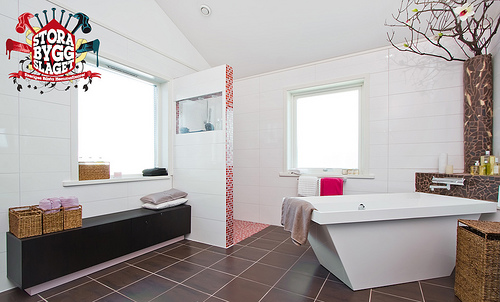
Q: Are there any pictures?
A: No, there are no pictures.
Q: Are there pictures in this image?
A: No, there are no pictures.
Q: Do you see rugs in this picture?
A: No, there are no rugs.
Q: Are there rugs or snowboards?
A: No, there are no rugs or snowboards.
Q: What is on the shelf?
A: The basket is on the shelf.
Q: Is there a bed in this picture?
A: No, there are no beds.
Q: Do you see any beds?
A: No, there are no beds.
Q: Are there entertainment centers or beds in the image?
A: No, there are no beds or entertainment centers.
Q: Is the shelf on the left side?
A: Yes, the shelf is on the left of the image.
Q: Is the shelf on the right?
A: No, the shelf is on the left of the image.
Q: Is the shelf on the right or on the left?
A: The shelf is on the left of the image.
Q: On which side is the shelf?
A: The shelf is on the left of the image.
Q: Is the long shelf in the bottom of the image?
A: Yes, the shelf is in the bottom of the image.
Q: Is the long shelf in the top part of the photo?
A: No, the shelf is in the bottom of the image.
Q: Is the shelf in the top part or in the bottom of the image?
A: The shelf is in the bottom of the image.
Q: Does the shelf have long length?
A: Yes, the shelf is long.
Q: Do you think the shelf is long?
A: Yes, the shelf is long.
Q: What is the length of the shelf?
A: The shelf is long.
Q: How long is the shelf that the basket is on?
A: The shelf is long.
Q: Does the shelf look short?
A: No, the shelf is long.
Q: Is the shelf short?
A: No, the shelf is long.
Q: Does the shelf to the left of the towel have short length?
A: No, the shelf is long.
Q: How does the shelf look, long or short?
A: The shelf is long.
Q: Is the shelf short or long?
A: The shelf is long.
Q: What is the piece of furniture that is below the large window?
A: The piece of furniture is a shelf.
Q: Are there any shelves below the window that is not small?
A: Yes, there is a shelf below the window.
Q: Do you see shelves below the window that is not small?
A: Yes, there is a shelf below the window.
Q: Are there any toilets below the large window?
A: No, there is a shelf below the window.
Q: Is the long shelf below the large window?
A: Yes, the shelf is below the window.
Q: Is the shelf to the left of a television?
A: No, the shelf is to the left of the towel.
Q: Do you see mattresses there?
A: No, there are no mattresses.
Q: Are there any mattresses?
A: No, there are no mattresses.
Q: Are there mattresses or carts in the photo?
A: No, there are no mattresses or carts.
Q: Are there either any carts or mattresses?
A: No, there are no mattresses or carts.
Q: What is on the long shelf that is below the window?
A: The basket is on the shelf.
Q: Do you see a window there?
A: Yes, there is a window.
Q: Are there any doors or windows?
A: Yes, there is a window.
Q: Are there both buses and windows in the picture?
A: No, there is a window but no buses.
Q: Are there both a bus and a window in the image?
A: No, there is a window but no buses.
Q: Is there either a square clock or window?
A: Yes, there is a square window.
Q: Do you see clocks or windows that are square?
A: Yes, the window is square.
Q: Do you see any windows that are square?
A: Yes, there is a square window.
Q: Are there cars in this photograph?
A: No, there are no cars.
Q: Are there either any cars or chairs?
A: No, there are no cars or chairs.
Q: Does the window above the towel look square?
A: Yes, the window is square.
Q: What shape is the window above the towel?
A: The window is square.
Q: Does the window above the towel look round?
A: No, the window is square.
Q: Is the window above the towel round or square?
A: The window is square.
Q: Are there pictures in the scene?
A: No, there are no pictures.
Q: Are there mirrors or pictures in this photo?
A: No, there are no pictures or mirrors.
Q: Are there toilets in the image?
A: No, there are no toilets.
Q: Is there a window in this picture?
A: Yes, there is a window.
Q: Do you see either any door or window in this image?
A: Yes, there is a window.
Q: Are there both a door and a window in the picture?
A: No, there is a window but no doors.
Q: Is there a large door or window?
A: Yes, there is a large window.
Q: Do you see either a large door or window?
A: Yes, there is a large window.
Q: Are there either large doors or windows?
A: Yes, there is a large window.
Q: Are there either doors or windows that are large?
A: Yes, the window is large.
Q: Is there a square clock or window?
A: Yes, there is a square window.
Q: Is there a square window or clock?
A: Yes, there is a square window.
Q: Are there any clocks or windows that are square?
A: Yes, the window is square.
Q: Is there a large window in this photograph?
A: Yes, there is a large window.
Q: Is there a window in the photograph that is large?
A: Yes, there is a window that is large.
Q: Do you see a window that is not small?
A: Yes, there is a large window.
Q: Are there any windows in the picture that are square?
A: Yes, there is a square window.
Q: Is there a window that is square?
A: Yes, there is a window that is square.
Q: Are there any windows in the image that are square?
A: Yes, there is a window that is square.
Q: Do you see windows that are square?
A: Yes, there is a window that is square.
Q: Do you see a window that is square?
A: Yes, there is a window that is square.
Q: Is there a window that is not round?
A: Yes, there is a square window.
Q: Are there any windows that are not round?
A: Yes, there is a square window.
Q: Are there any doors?
A: No, there are no doors.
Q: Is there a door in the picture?
A: No, there are no doors.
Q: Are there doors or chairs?
A: No, there are no doors or chairs.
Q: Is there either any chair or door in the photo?
A: No, there are no doors or chairs.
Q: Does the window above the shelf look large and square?
A: Yes, the window is large and square.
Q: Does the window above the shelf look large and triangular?
A: No, the window is large but square.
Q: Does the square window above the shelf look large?
A: Yes, the window is large.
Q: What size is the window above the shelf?
A: The window is large.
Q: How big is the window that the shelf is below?
A: The window is large.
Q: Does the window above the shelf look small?
A: No, the window is large.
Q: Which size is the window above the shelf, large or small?
A: The window is large.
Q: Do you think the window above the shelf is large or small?
A: The window is large.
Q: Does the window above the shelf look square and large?
A: Yes, the window is square and large.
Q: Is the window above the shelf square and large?
A: Yes, the window is square and large.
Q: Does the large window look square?
A: Yes, the window is square.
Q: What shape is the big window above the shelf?
A: The window is square.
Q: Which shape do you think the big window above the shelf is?
A: The window is square.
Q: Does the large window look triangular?
A: No, the window is square.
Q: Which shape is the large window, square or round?
A: The window is square.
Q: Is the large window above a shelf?
A: Yes, the window is above a shelf.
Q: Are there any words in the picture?
A: Yes, there are words.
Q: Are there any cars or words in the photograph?
A: Yes, there are words.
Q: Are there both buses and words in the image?
A: No, there are words but no buses.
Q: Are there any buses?
A: No, there are no buses.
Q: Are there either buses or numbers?
A: No, there are no buses or numbers.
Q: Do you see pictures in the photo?
A: No, there are no pictures.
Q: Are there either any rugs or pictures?
A: No, there are no pictures or rugs.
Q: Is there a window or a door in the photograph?
A: Yes, there is a window.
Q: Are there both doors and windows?
A: No, there is a window but no doors.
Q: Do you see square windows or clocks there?
A: Yes, there is a square window.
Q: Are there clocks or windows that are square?
A: Yes, the window is square.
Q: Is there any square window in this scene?
A: Yes, there is a square window.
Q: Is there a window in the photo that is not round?
A: Yes, there is a square window.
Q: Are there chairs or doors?
A: No, there are no doors or chairs.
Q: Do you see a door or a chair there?
A: No, there are no doors or chairs.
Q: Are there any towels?
A: Yes, there is a towel.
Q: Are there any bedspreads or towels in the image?
A: Yes, there is a towel.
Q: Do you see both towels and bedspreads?
A: No, there is a towel but no bedspreads.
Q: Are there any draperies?
A: No, there are no draperies.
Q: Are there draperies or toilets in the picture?
A: No, there are no draperies or toilets.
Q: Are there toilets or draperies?
A: No, there are no draperies or toilets.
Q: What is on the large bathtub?
A: The towel is on the tub.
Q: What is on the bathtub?
A: The towel is on the tub.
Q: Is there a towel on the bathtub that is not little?
A: Yes, there is a towel on the bathtub.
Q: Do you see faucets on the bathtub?
A: No, there is a towel on the bathtub.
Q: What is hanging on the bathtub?
A: The towel is hanging on the bathtub.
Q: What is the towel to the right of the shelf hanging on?
A: The towel is hanging on the bath tub.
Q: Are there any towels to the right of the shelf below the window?
A: Yes, there is a towel to the right of the shelf.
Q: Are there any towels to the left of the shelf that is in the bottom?
A: No, the towel is to the right of the shelf.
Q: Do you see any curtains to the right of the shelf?
A: No, there is a towel to the right of the shelf.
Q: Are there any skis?
A: No, there are no skis.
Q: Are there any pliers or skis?
A: No, there are no skis or pliers.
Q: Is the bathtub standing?
A: Yes, the bathtub is standing.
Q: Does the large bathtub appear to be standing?
A: Yes, the bathtub is standing.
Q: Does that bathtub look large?
A: Yes, the bathtub is large.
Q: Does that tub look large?
A: Yes, the tub is large.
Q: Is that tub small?
A: No, the tub is large.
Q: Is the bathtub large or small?
A: The bathtub is large.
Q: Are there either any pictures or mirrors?
A: No, there are no pictures or mirrors.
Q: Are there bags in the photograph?
A: No, there are no bags.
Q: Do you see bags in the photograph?
A: No, there are no bags.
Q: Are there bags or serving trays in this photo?
A: No, there are no bags or serving trays.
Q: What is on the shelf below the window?
A: The basket is on the shelf.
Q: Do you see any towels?
A: Yes, there is a towel.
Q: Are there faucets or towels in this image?
A: Yes, there is a towel.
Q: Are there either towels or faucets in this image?
A: Yes, there is a towel.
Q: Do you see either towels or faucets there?
A: Yes, there is a towel.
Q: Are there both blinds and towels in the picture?
A: No, there is a towel but no blinds.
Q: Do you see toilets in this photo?
A: No, there are no toilets.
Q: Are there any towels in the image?
A: Yes, there is a towel.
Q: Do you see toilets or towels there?
A: Yes, there is a towel.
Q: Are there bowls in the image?
A: No, there are no bowls.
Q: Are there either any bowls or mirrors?
A: No, there are no bowls or mirrors.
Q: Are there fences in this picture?
A: No, there are no fences.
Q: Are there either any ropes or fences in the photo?
A: No, there are no fences or ropes.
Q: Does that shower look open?
A: Yes, the shower is open.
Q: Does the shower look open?
A: Yes, the shower is open.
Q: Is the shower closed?
A: No, the shower is open.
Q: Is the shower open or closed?
A: The shower is open.